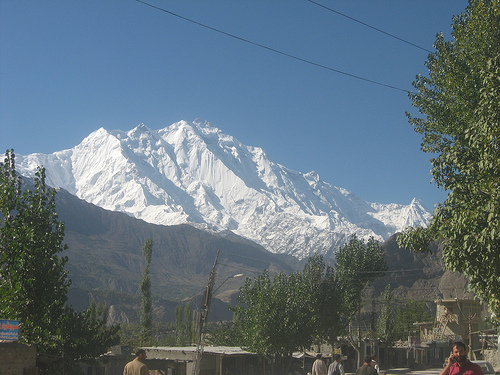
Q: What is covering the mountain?
A: White snow.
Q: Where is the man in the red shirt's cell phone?
A: In hand near ear.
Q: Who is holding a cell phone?
A: The man in a red shirt.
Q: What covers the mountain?
A: Snow.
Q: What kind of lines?
A: Power.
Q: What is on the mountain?
A: Snow.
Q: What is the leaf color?
A: Green.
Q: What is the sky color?
A: Blue.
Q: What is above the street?
A: Power lines.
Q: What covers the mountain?
A: Snow.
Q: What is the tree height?
A: Tall.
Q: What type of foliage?
A: Trees.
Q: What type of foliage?
A: Tree.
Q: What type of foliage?
A: Tree.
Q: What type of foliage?
A: Tree.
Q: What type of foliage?
A: Tree.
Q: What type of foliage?
A: Tree.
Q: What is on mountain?
A: Snow.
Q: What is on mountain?
A: Snow.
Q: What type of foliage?
A: Trees.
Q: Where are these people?
A: Mountain stop.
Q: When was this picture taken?
A: Daylight.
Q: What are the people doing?
A: Walking.